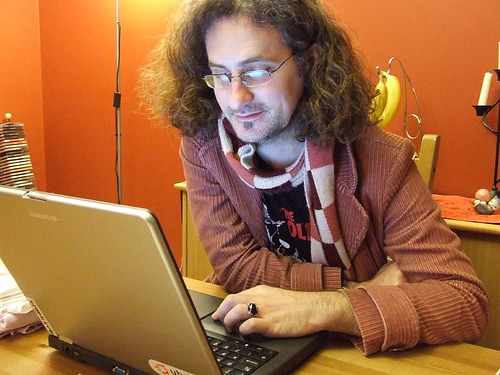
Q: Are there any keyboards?
A: Yes, there is a keyboard.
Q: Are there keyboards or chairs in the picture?
A: Yes, there is a keyboard.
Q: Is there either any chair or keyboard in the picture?
A: Yes, there is a keyboard.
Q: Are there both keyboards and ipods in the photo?
A: No, there is a keyboard but no ipods.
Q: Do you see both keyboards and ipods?
A: No, there is a keyboard but no ipods.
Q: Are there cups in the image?
A: No, there are no cups.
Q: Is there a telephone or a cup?
A: No, there are no cups or phones.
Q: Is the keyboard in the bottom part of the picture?
A: Yes, the keyboard is in the bottom of the image.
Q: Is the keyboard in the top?
A: No, the keyboard is in the bottom of the image.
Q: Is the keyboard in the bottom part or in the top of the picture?
A: The keyboard is in the bottom of the image.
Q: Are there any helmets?
A: No, there are no helmets.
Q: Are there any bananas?
A: Yes, there are bananas.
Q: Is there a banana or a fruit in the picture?
A: Yes, there are bananas.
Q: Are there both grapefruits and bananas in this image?
A: No, there are bananas but no grapefruits.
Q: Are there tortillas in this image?
A: No, there are no tortillas.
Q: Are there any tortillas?
A: No, there are no tortillas.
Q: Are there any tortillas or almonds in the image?
A: No, there are no tortillas or almonds.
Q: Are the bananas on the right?
A: Yes, the bananas are on the right of the image.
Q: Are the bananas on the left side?
A: No, the bananas are on the right of the image.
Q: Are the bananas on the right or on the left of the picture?
A: The bananas are on the right of the image.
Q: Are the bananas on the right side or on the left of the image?
A: The bananas are on the right of the image.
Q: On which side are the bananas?
A: The bananas are on the right of the image.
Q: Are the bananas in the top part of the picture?
A: Yes, the bananas are in the top of the image.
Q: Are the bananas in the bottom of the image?
A: No, the bananas are in the top of the image.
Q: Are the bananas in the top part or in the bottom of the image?
A: The bananas are in the top of the image.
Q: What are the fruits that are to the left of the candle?
A: The fruits are bananas.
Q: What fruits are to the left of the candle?
A: The fruits are bananas.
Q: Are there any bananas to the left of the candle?
A: Yes, there are bananas to the left of the candle.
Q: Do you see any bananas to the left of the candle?
A: Yes, there are bananas to the left of the candle.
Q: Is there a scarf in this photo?
A: Yes, there is a scarf.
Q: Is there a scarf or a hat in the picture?
A: Yes, there is a scarf.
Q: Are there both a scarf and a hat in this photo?
A: No, there is a scarf but no hats.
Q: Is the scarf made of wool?
A: Yes, the scarf is made of wool.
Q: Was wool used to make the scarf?
A: Yes, the scarf is made of wool.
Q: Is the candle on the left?
A: No, the candle is on the right of the image.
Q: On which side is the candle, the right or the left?
A: The candle is on the right of the image.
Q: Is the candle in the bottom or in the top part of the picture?
A: The candle is in the top of the image.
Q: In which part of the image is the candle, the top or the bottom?
A: The candle is in the top of the image.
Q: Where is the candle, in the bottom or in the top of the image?
A: The candle is in the top of the image.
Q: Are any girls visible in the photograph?
A: No, there are no girls.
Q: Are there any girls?
A: No, there are no girls.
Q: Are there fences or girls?
A: No, there are no girls or fences.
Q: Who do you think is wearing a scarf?
A: The man is wearing a scarf.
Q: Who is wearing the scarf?
A: The man is wearing a scarf.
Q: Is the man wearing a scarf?
A: Yes, the man is wearing a scarf.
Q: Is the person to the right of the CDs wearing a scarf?
A: Yes, the man is wearing a scarf.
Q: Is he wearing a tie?
A: No, the man is wearing a scarf.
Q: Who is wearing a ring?
A: The man is wearing a ring.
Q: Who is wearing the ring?
A: The man is wearing a ring.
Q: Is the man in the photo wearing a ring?
A: Yes, the man is wearing a ring.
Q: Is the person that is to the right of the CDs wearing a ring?
A: Yes, the man is wearing a ring.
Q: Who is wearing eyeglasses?
A: The man is wearing eyeglasses.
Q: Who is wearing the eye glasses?
A: The man is wearing eyeglasses.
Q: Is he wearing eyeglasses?
A: Yes, the man is wearing eyeglasses.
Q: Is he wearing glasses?
A: No, the man is wearing eyeglasses.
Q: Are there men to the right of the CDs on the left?
A: Yes, there is a man to the right of the CDs.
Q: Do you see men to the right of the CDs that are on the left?
A: Yes, there is a man to the right of the CDs.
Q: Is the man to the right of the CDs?
A: Yes, the man is to the right of the CDs.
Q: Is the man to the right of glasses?
A: No, the man is to the right of the CDs.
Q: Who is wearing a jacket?
A: The man is wearing a jacket.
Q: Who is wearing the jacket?
A: The man is wearing a jacket.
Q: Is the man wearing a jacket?
A: Yes, the man is wearing a jacket.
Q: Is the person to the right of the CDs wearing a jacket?
A: Yes, the man is wearing a jacket.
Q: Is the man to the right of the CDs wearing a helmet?
A: No, the man is wearing a jacket.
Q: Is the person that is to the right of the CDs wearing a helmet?
A: No, the man is wearing a jacket.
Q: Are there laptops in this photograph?
A: Yes, there is a laptop.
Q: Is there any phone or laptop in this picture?
A: Yes, there is a laptop.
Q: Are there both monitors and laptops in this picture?
A: No, there is a laptop but no monitors.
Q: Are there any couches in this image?
A: No, there are no couches.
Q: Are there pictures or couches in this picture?
A: No, there are no couches or pictures.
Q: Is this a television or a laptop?
A: This is a laptop.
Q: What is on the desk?
A: The laptop is on the desk.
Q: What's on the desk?
A: The laptop is on the desk.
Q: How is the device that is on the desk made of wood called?
A: The device is a laptop.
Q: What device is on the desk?
A: The device is a laptop.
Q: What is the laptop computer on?
A: The laptop computer is on the desk.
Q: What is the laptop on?
A: The laptop computer is on the desk.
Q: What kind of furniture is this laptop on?
A: The laptop is on the desk.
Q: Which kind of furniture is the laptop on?
A: The laptop is on the desk.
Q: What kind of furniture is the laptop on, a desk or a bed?
A: The laptop is on a desk.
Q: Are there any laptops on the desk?
A: Yes, there is a laptop on the desk.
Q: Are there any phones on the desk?
A: No, there is a laptop on the desk.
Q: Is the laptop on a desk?
A: Yes, the laptop is on a desk.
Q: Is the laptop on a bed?
A: No, the laptop is on a desk.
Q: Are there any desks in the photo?
A: Yes, there is a desk.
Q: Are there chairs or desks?
A: Yes, there is a desk.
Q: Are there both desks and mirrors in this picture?
A: No, there is a desk but no mirrors.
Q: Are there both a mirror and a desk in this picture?
A: No, there is a desk but no mirrors.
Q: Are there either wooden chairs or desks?
A: Yes, there is a wood desk.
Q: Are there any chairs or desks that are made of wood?
A: Yes, the desk is made of wood.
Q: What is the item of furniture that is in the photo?
A: The piece of furniture is a desk.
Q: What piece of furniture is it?
A: The piece of furniture is a desk.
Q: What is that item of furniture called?
A: This is a desk.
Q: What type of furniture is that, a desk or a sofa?
A: This is a desk.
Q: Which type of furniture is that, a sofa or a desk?
A: This is a desk.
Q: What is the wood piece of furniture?
A: The piece of furniture is a desk.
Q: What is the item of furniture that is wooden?
A: The piece of furniture is a desk.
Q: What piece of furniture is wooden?
A: The piece of furniture is a desk.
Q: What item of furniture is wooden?
A: The piece of furniture is a desk.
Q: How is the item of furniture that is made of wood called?
A: The piece of furniture is a desk.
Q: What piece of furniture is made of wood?
A: The piece of furniture is a desk.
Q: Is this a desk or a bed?
A: This is a desk.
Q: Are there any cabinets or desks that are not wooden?
A: No, there is a desk but it is wooden.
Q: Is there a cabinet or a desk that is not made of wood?
A: No, there is a desk but it is made of wood.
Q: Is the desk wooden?
A: Yes, the desk is wooden.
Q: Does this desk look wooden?
A: Yes, the desk is wooden.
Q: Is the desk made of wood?
A: Yes, the desk is made of wood.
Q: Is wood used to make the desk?
A: Yes, the desk is made of wood.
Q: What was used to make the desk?
A: The desk is made of wood.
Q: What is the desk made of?
A: The desk is made of wood.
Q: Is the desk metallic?
A: No, the desk is wooden.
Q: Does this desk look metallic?
A: No, the desk is wooden.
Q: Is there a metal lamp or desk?
A: No, there is a desk but it is wooden.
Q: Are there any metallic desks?
A: No, there is a desk but it is wooden.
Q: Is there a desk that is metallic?
A: No, there is a desk but it is wooden.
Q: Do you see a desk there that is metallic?
A: No, there is a desk but it is wooden.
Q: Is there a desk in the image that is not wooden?
A: No, there is a desk but it is wooden.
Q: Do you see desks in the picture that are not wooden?
A: No, there is a desk but it is wooden.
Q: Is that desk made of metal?
A: No, the desk is made of wood.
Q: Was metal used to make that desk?
A: No, the desk is made of wood.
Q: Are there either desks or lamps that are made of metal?
A: No, there is a desk but it is made of wood.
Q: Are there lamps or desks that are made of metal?
A: No, there is a desk but it is made of wood.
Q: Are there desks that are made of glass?
A: No, there is a desk but it is made of wood.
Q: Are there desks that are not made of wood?
A: No, there is a desk but it is made of wood.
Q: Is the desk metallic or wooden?
A: The desk is wooden.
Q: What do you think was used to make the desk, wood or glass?
A: The desk is made of wood.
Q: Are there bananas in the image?
A: Yes, there is a banana.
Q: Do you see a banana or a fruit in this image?
A: Yes, there is a banana.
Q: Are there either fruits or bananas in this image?
A: Yes, there is a banana.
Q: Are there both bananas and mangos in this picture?
A: No, there is a banana but no mangoes.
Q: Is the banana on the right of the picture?
A: Yes, the banana is on the right of the image.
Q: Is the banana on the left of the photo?
A: No, the banana is on the right of the image.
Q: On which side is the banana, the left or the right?
A: The banana is on the right of the image.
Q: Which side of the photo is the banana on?
A: The banana is on the right of the image.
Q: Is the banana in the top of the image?
A: Yes, the banana is in the top of the image.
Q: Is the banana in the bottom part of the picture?
A: No, the banana is in the top of the image.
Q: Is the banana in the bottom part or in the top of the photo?
A: The banana is in the top of the image.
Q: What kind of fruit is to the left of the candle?
A: The fruit is a banana.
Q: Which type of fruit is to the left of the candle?
A: The fruit is a banana.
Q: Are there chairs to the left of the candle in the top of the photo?
A: No, there is a banana to the left of the candle.